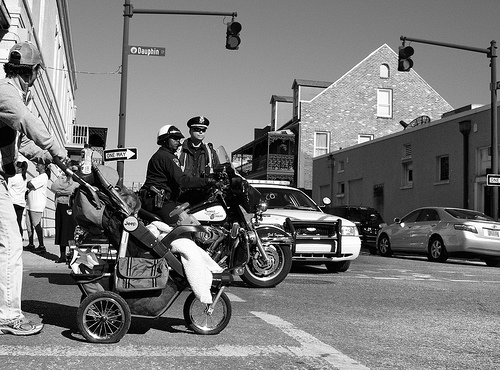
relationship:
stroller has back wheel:
[43, 144, 240, 346] [73, 288, 133, 345]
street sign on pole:
[125, 44, 171, 58] [109, 3, 139, 195]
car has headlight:
[238, 174, 360, 275] [339, 222, 360, 238]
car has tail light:
[374, 203, 499, 264] [452, 221, 478, 235]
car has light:
[238, 174, 360, 275] [240, 178, 294, 187]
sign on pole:
[99, 144, 143, 165] [109, 3, 139, 195]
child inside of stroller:
[112, 181, 148, 222] [43, 144, 240, 346]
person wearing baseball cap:
[0, 40, 74, 342] [9, 41, 51, 72]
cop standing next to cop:
[176, 112, 223, 188] [138, 122, 220, 226]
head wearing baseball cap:
[3, 39, 51, 91] [9, 41, 51, 72]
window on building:
[374, 85, 397, 121] [289, 43, 463, 196]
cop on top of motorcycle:
[138, 122, 220, 226] [67, 140, 295, 286]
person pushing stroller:
[0, 40, 74, 342] [43, 144, 240, 346]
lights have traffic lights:
[221, 10, 243, 56] [226, 20, 244, 49]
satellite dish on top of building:
[395, 113, 434, 135] [307, 97, 497, 214]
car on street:
[238, 174, 360, 275] [0, 207, 497, 369]